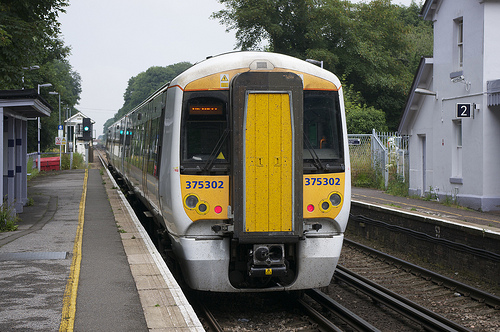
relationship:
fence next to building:
[349, 134, 409, 185] [397, 1, 499, 211]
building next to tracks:
[397, 1, 499, 211] [347, 247, 486, 330]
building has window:
[397, 1, 499, 211] [451, 115, 465, 182]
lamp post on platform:
[35, 82, 52, 172] [0, 166, 89, 330]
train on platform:
[101, 49, 356, 293] [0, 166, 89, 330]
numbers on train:
[300, 172, 341, 185] [101, 49, 356, 293]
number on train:
[218, 181, 224, 189] [101, 49, 356, 293]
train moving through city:
[101, 49, 356, 293] [7, 33, 487, 293]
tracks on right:
[310, 271, 465, 328] [365, 6, 484, 326]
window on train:
[181, 83, 234, 179] [101, 49, 356, 293]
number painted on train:
[177, 178, 229, 194] [84, 32, 357, 314]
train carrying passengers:
[101, 49, 356, 293] [99, 122, 172, 171]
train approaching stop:
[101, 49, 356, 293] [175, 115, 389, 317]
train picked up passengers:
[116, 89, 361, 294] [99, 111, 176, 193]